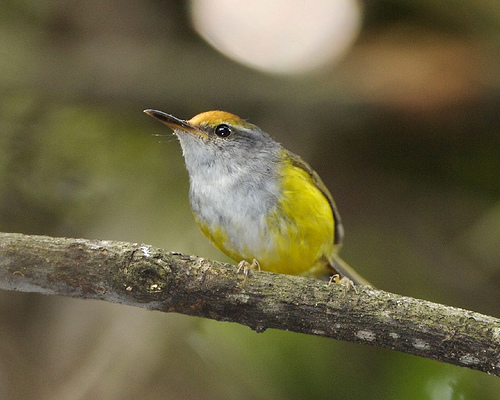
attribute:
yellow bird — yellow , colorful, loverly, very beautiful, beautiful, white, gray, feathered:
[142, 103, 369, 285]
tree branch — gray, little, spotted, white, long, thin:
[1, 230, 499, 377]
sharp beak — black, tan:
[143, 108, 188, 132]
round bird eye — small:
[213, 123, 230, 138]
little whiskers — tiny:
[150, 129, 177, 149]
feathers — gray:
[319, 249, 373, 290]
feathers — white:
[171, 128, 296, 265]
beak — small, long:
[141, 106, 205, 136]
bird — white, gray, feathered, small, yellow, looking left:
[144, 103, 376, 289]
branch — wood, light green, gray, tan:
[0, 229, 499, 378]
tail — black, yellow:
[324, 251, 377, 290]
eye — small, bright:
[212, 124, 235, 139]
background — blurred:
[1, 0, 498, 398]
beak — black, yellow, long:
[144, 106, 207, 142]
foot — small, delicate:
[234, 255, 260, 278]